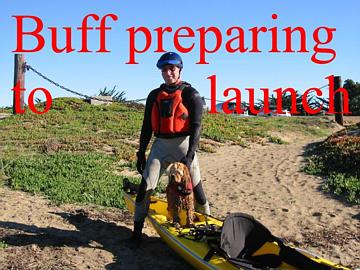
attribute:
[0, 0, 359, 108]
sky — clear, blue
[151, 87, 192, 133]
life vest — orange, black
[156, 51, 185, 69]
helmet — blue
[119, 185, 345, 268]
kayak — yellow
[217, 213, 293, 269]
kayak seat — black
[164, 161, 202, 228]
dog — brown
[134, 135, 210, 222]
pants — gray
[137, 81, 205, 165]
top — black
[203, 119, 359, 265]
road — sandy